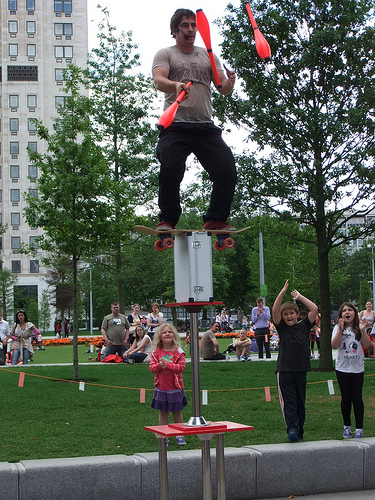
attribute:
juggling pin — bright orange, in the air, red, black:
[244, 2, 271, 61]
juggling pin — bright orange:
[196, 9, 223, 88]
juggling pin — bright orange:
[158, 80, 192, 127]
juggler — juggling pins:
[153, 8, 240, 233]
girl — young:
[149, 322, 187, 447]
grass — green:
[1, 329, 374, 463]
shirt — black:
[270, 315, 316, 373]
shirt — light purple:
[252, 307, 273, 329]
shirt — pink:
[157, 348, 175, 390]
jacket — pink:
[150, 345, 186, 392]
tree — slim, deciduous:
[23, 55, 136, 380]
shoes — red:
[157, 219, 236, 231]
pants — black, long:
[157, 122, 238, 225]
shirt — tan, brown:
[152, 45, 225, 124]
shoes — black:
[288, 430, 304, 442]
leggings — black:
[335, 369, 365, 427]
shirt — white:
[331, 322, 365, 374]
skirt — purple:
[151, 387, 189, 410]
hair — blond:
[153, 322, 182, 353]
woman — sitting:
[121, 325, 154, 363]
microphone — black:
[175, 28, 188, 40]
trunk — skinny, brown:
[71, 98, 80, 383]